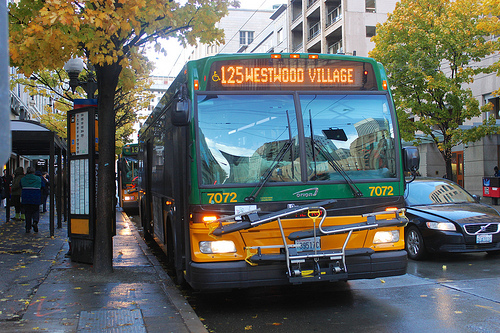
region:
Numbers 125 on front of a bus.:
[220, 65, 244, 85]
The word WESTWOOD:
[242, 65, 304, 82]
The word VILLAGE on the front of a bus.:
[307, 67, 353, 82]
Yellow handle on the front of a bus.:
[305, 207, 321, 219]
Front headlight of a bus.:
[198, 239, 235, 255]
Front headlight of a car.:
[424, 219, 456, 231]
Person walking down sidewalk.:
[20, 165, 45, 232]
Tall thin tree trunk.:
[89, 61, 116, 275]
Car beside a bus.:
[402, 173, 498, 258]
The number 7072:
[367, 185, 394, 198]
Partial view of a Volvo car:
[405, 178, 499, 253]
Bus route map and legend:
[66, 108, 94, 259]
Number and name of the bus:
[215, 58, 359, 87]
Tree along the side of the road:
[371, 1, 496, 181]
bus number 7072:
[200, 188, 239, 203]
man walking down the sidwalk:
[13, 166, 48, 236]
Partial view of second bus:
[117, 141, 142, 215]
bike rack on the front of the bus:
[251, 205, 378, 282]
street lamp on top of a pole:
[59, 56, 91, 95]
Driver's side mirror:
[401, 143, 423, 172]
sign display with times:
[59, 103, 99, 262]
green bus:
[140, 49, 415, 296]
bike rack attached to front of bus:
[240, 203, 392, 286]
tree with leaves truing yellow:
[377, 7, 487, 179]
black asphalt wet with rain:
[309, 289, 441, 329]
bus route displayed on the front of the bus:
[206, 52, 379, 89]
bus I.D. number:
[198, 169, 248, 211]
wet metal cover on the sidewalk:
[79, 301, 144, 331]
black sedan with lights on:
[404, 171, 499, 267]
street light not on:
[63, 43, 89, 90]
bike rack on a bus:
[208, 194, 411, 284]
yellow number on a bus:
[200, 187, 243, 208]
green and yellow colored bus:
[134, 47, 416, 302]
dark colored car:
[397, 167, 499, 263]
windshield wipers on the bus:
[245, 134, 361, 206]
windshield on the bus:
[196, 86, 399, 196]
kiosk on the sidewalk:
[61, 90, 121, 269]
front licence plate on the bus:
[289, 230, 321, 252]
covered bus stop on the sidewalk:
[1, 112, 64, 231]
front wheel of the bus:
[163, 209, 186, 286]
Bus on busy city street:
[27, 11, 484, 326]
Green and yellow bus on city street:
[86, 26, 457, 310]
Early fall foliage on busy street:
[3, 1, 499, 144]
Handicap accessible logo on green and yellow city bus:
[188, 55, 229, 94]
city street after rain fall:
[3, 182, 494, 331]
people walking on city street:
[4, 160, 56, 237]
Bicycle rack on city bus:
[210, 205, 416, 283]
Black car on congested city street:
[401, 170, 498, 276]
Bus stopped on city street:
[18, 12, 204, 312]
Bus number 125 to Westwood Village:
[182, 36, 419, 295]